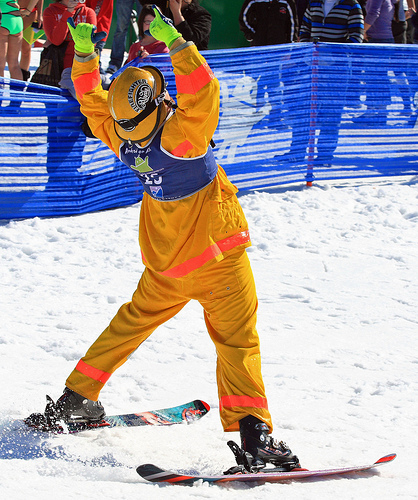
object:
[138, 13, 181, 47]
gloves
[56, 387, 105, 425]
boot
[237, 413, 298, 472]
boot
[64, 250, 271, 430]
pants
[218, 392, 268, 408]
reflective material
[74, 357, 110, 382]
reflective material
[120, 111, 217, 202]
vest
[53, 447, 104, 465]
snow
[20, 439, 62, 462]
spraying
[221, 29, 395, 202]
fence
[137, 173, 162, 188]
number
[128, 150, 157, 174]
robot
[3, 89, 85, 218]
fence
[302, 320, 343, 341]
white snow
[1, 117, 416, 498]
ground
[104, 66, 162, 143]
helmet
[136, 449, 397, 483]
ski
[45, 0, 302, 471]
skier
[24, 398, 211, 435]
ski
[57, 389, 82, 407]
strap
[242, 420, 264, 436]
strap